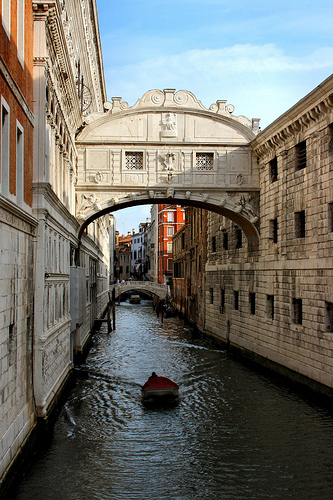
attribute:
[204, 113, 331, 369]
water stains — dark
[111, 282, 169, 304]
bridge — short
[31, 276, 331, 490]
water — gray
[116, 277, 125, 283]
people — walking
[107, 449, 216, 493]
water — murky, dark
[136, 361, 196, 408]
boat — White and red 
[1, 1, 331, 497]
river — flows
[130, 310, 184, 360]
river — flows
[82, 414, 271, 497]
ripples — wide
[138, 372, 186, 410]
man — sailing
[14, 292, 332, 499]
watersurface — Still grey 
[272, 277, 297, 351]
wall — small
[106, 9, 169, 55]
patch sky — blue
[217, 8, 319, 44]
patch sky — blue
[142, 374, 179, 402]
boat — small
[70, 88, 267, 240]
bridge — ornate covered, White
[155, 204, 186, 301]
building — tan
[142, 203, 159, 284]
building — tan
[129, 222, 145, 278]
building — tan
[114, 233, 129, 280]
building — tan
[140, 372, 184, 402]
boat — brown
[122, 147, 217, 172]
windows — closed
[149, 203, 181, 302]
building — Red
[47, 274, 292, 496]
water — Still grey 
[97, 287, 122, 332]
dock — small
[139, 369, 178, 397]
boat — small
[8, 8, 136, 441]
building — white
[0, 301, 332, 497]
water surface — Still grey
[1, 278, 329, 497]
canal — long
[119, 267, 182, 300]
bridge — short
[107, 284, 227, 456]
canal — long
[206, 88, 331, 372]
building wall — Small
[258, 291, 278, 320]
window — closed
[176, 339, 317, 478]
surface — gray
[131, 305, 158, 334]
water — grey